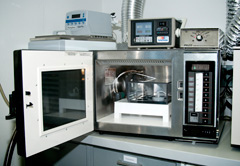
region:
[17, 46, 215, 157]
this is a oven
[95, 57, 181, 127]
the oven is opened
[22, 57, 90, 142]
the ovens door is white in color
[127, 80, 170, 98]
a metallic container is inside the oven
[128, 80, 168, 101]
the metallic container is shiny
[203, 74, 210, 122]
these are buttons on the oven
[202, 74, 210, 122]
the buttons are black in color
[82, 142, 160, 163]
the oven is on a stand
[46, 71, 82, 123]
this is made of glass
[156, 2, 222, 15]
the wall is white in color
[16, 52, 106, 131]
Open door of microwave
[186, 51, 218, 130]
Control panel for microwave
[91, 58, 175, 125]
inside of microwave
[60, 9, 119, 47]
Medical equipment for microwave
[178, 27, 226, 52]
Microwave reciever equiptment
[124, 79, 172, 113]
Dish in microwave ready to be heated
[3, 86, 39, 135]
Microwave side door lock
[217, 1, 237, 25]
Metallic tubing running up and down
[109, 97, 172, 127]
Small white microwave table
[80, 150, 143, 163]
A drawer with a white label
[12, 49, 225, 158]
an autoclave used for sterilization of equipment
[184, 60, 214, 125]
an autoclave control panel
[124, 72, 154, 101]
a labaratory metal container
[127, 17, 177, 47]
an electronic monitoring device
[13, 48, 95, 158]
an autoclave open door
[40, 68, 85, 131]
an autoclave glass window for observation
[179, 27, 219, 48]
an electronic monitor with a beige front and a black dial with numbers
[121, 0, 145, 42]
a silver air ventilation duct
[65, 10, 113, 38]
a blue and grey electronic device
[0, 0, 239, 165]
a scene of a laboratory with some lab equipment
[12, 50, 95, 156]
Door of the machine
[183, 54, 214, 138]
Buttons that displays several options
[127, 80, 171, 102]
Glass container inside of the machine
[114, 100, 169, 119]
Solid stand that holds the glass container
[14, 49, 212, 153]
Machine apparatus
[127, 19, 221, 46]
Several devices on top of the machine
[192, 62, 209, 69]
Digital display that lists the option currently selected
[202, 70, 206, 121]
Buttons that chooses several options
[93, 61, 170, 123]
Inside of machine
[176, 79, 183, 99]
Small slots that connects the door of the machine to the machine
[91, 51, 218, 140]
a microwave on the counter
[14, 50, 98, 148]
the open door of the microwave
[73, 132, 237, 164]
the counter the microwave is on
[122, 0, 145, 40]
a pipe next to the wall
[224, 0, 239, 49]
another pipe next to the wall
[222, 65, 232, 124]
a power cord behind all the devices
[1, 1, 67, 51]
part of the grey wall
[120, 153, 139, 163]
a name tag on the drawer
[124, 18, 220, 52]
boxes sitting on top of the microwave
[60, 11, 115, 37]
another box sitting next to the microwave